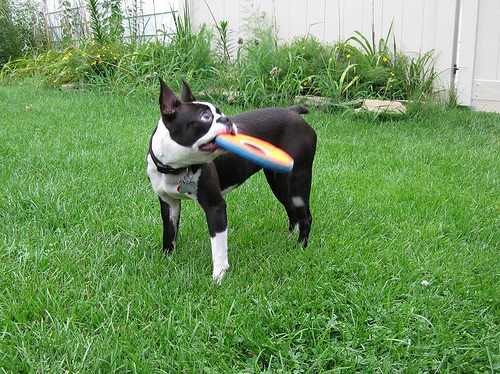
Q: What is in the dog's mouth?
A: Frisbee.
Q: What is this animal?
A: Dog.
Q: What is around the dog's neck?
A: Collar.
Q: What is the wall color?
A: White.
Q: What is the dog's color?
A: Black and white.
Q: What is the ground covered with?
A: Grass.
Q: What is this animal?
A: Dog.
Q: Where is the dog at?
A: Backyard.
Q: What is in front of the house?
A: Grass and flowers.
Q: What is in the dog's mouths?
A: Frisbee.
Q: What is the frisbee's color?
A: Rainbow.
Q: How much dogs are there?
A: 1.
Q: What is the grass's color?
A: Green.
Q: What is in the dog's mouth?
A: A frisbee.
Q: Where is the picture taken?
A: A yard.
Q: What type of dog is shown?
A: Rottweiler.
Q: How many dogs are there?
A: One.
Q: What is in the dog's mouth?
A: A frisbee.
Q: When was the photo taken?
A: Daytime.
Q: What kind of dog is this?
A: Boston Terrier.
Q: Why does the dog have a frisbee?
A: He's playing.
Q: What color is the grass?
A: Green.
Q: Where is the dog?
A: In the backyard.